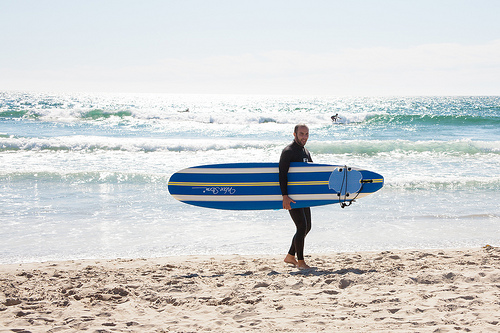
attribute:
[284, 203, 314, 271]
legs — male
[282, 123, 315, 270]
man — one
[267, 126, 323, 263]
person — one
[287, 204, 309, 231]
wet suit — one, black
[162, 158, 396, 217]
surfboard — one, large, blue, white 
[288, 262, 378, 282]
shadow — male, one, human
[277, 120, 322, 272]
man — one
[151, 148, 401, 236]
surfboard — one, surf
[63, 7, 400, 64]
sky — blue, distant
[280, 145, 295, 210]
arm — one, human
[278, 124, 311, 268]
man — one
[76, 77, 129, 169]
waves — some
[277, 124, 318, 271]
man — one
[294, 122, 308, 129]
hair — short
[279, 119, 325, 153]
facial hair — some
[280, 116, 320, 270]
person — one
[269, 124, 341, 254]
man — standing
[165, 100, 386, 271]
person — one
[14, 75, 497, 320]
beach — sandy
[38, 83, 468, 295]
water — some, wavy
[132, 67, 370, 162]
waves — some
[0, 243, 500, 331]
sand — some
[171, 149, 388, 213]
board — blue, white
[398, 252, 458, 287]
sand — beach, some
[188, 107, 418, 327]
man — one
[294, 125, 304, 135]
dark hair — some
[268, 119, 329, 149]
head — human, male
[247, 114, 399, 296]
man — one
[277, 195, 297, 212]
hand — one, male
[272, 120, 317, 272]
man — one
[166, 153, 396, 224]
surfboard — one , blue, white 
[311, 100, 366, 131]
person — one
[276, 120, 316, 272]
person — one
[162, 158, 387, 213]
surfboard — one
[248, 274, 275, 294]
track — sandy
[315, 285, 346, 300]
track — sandy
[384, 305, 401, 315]
track — sandy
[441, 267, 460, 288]
track — sandy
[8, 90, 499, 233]
water — bright, blue, some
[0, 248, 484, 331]
beach — brown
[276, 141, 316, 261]
wetsuit — black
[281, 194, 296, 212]
fingers — some, male